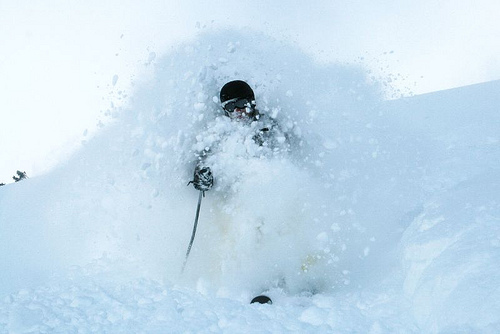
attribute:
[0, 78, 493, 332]
snow — body, large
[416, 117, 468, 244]
snow — large, body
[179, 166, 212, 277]
pole — black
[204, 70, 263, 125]
goggles — pair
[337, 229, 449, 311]
snow — large, body